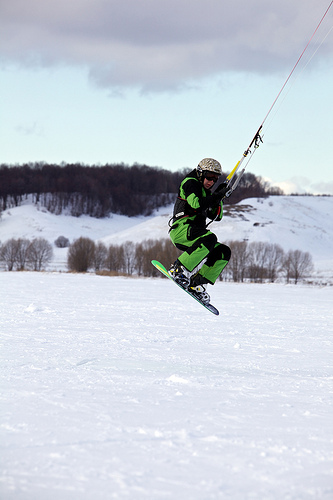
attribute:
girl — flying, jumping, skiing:
[183, 146, 235, 284]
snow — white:
[81, 311, 167, 374]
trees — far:
[59, 145, 123, 222]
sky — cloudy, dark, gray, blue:
[95, 58, 155, 104]